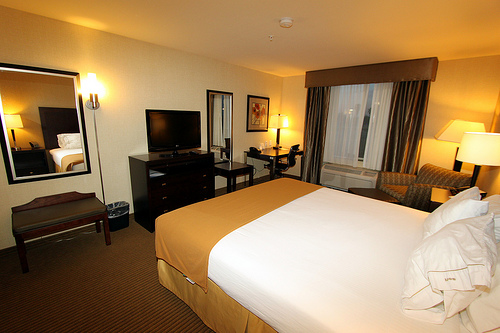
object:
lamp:
[267, 114, 290, 150]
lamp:
[454, 131, 500, 201]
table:
[11, 146, 49, 177]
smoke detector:
[278, 18, 294, 29]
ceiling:
[0, 0, 500, 80]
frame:
[243, 94, 270, 133]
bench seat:
[10, 191, 112, 273]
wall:
[0, 7, 281, 250]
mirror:
[0, 62, 92, 184]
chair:
[374, 162, 472, 212]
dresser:
[127, 149, 216, 233]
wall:
[275, 77, 308, 181]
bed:
[152, 176, 499, 332]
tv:
[144, 108, 202, 154]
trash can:
[103, 201, 130, 232]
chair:
[264, 137, 300, 178]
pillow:
[400, 212, 496, 324]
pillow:
[416, 185, 489, 238]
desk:
[240, 146, 304, 186]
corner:
[254, 71, 308, 179]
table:
[429, 187, 484, 213]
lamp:
[77, 71, 107, 230]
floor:
[0, 176, 484, 331]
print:
[248, 97, 268, 130]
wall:
[415, 54, 500, 168]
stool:
[214, 160, 254, 193]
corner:
[437, 50, 500, 207]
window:
[322, 81, 398, 172]